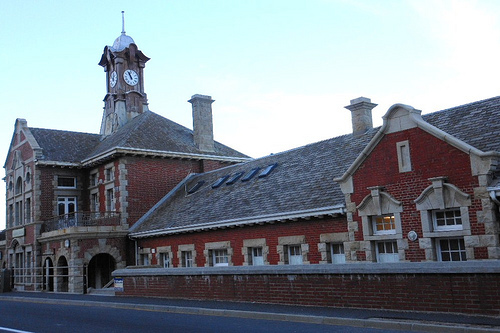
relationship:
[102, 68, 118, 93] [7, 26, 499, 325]
clock on building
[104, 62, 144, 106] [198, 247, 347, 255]
clock faces on building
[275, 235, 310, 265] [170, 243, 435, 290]
window in a row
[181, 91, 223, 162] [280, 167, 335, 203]
chimney on grey roof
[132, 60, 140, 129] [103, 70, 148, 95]
hands on clock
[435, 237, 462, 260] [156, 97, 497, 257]
window on building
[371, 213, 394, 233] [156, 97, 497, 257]
window on building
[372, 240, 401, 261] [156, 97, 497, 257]
window on building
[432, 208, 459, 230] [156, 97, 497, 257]
window on building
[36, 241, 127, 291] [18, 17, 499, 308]
archways on building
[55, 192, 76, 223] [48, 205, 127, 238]
door on balcony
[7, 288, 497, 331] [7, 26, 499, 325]
sidewalk in front of building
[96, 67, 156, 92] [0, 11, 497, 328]
clock on top of building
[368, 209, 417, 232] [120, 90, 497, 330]
light in building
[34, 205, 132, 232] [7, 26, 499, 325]
balcony on building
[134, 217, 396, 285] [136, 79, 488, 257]
windows on building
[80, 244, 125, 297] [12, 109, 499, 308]
archways to building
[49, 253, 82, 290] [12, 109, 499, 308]
entrance to building